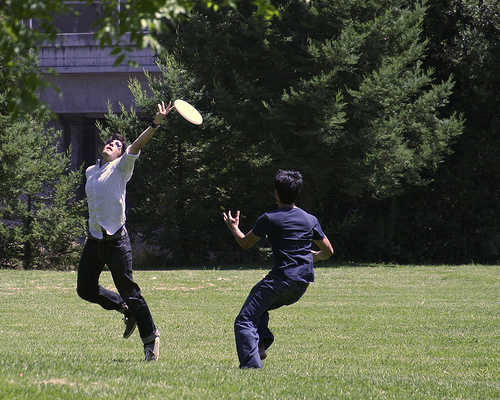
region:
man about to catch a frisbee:
[60, 92, 212, 349]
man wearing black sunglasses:
[96, 133, 137, 150]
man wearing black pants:
[61, 226, 169, 328]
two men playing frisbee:
[58, 96, 340, 379]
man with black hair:
[256, 166, 314, 210]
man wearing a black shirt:
[247, 208, 324, 278]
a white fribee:
[172, 86, 212, 130]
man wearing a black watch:
[146, 118, 165, 137]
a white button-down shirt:
[81, 155, 147, 232]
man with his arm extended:
[81, 86, 207, 188]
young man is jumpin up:
[75, 97, 177, 349]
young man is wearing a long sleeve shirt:
[82, 145, 138, 240]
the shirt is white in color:
[83, 143, 135, 238]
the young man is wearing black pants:
[71, 223, 159, 342]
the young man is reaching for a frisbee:
[70, 97, 177, 187]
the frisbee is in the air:
[171, 96, 206, 125]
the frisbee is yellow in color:
[172, 96, 204, 126]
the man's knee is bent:
[71, 231, 139, 320]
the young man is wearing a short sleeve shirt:
[253, 196, 325, 286]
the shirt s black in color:
[246, 208, 327, 279]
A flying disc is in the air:
[171, 85, 215, 146]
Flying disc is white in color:
[163, 89, 210, 136]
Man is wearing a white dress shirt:
[63, 145, 145, 252]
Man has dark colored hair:
[260, 156, 314, 223]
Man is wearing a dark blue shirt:
[238, 204, 338, 294]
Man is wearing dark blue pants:
[201, 256, 323, 376]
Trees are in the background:
[108, 1, 498, 263]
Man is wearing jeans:
[69, 228, 164, 352]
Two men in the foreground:
[67, 93, 366, 380]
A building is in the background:
[13, 4, 188, 170]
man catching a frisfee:
[39, 63, 198, 226]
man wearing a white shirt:
[73, 85, 199, 240]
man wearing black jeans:
[64, 98, 173, 373]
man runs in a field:
[193, 139, 343, 295]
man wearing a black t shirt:
[224, 150, 331, 312]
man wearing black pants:
[210, 139, 342, 387]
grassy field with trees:
[382, 195, 471, 399]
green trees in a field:
[330, 25, 455, 228]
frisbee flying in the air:
[162, 79, 207, 139]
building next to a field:
[51, 24, 137, 106]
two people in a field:
[43, 90, 373, 399]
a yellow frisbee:
[161, 72, 219, 145]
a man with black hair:
[268, 165, 316, 215]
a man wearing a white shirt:
[67, 97, 165, 299]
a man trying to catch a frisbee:
[44, 80, 204, 322]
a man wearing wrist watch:
[144, 96, 174, 155]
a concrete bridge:
[12, 21, 182, 157]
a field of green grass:
[330, 175, 473, 371]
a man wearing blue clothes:
[212, 137, 331, 371]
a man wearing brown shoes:
[126, 104, 170, 392]